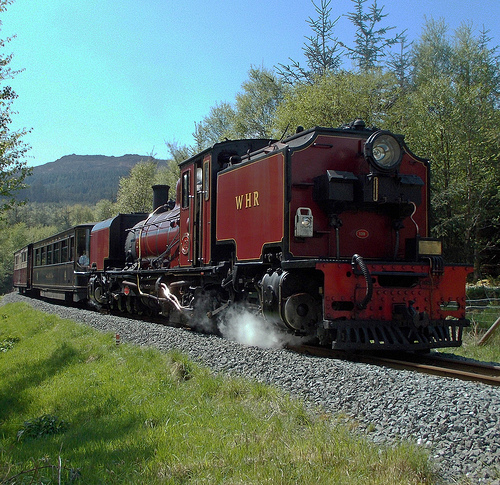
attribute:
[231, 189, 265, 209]
words — yellow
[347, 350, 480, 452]
place — rocky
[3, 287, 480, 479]
gravel — GRAY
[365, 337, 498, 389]
tracks — train tracks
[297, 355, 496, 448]
gravel — gray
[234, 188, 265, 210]
word — yellow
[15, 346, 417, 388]
floor — green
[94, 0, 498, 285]
forest — THICK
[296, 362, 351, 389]
stones —  several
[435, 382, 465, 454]
stones — small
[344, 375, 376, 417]
stones — small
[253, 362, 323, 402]
stones — small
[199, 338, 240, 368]
stones — small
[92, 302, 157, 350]
stones — small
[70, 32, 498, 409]
train — metallic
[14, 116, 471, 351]
train —  in motion, maroon, red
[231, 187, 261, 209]
words — yellow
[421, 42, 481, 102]
trees — green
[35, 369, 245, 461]
grass — GREEN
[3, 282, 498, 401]
tracks — train tracks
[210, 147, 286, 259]
plate —  maroon